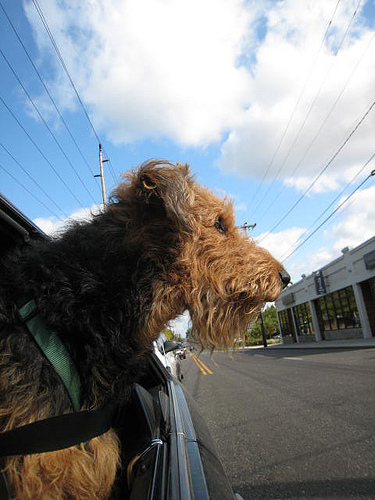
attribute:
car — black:
[0, 196, 245, 499]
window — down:
[2, 201, 179, 499]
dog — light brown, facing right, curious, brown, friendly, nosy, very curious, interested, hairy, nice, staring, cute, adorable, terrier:
[0, 156, 292, 496]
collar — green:
[13, 293, 87, 412]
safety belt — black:
[0, 390, 118, 455]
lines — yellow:
[182, 347, 211, 379]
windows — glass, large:
[278, 277, 375, 345]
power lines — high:
[1, 0, 122, 238]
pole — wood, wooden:
[92, 143, 114, 211]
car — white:
[152, 329, 184, 374]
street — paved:
[173, 343, 374, 500]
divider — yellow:
[179, 342, 215, 378]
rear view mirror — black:
[160, 338, 180, 354]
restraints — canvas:
[4, 288, 122, 454]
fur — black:
[80, 312, 178, 408]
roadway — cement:
[176, 343, 373, 499]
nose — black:
[274, 265, 292, 289]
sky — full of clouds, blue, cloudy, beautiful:
[0, 1, 374, 337]